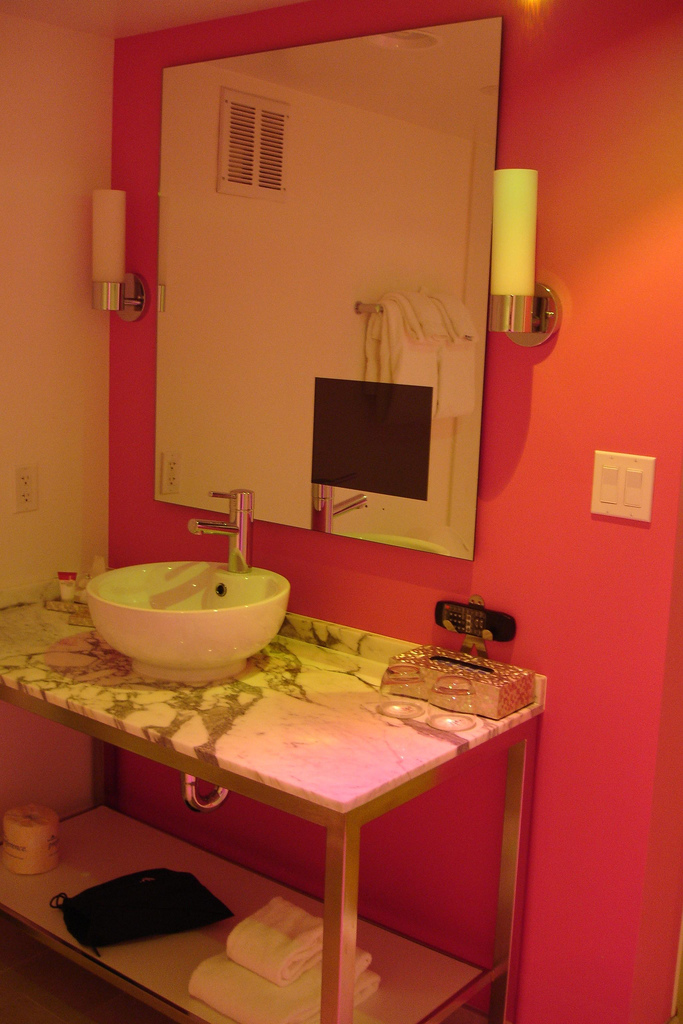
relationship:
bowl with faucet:
[85, 561, 290, 682] [188, 489, 255, 575]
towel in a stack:
[226, 895, 323, 987] [166, 926, 327, 1019]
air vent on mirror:
[207, 79, 291, 198] [153, 15, 501, 563]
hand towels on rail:
[365, 285, 479, 419] [354, 301, 384, 315]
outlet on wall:
[13, 462, 38, 514] [1, 301, 121, 584]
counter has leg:
[4, 599, 554, 821] [305, 808, 373, 1020]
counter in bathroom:
[4, 599, 554, 821] [9, 104, 678, 642]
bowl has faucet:
[85, 561, 290, 682] [181, 473, 261, 569]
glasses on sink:
[365, 647, 484, 733] [84, 553, 293, 684]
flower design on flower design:
[481, 648, 531, 711] [388, 644, 535, 720]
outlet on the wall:
[12, 461, 43, 518] [11, 21, 117, 597]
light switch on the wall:
[586, 442, 658, 527] [96, 32, 661, 1011]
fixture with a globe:
[92, 189, 150, 322] [90, 183, 134, 279]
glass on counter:
[376, 661, 426, 726] [7, 543, 547, 811]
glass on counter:
[422, 671, 479, 731] [4, 599, 554, 821]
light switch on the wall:
[591, 450, 656, 523] [96, 32, 661, 1011]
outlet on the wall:
[13, 462, 38, 514] [8, 47, 109, 892]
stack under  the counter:
[187, 896, 380, 1024] [6, 510, 551, 810]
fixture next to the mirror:
[92, 189, 150, 322] [146, 12, 518, 562]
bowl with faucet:
[85, 561, 290, 682] [183, 486, 258, 569]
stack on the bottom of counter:
[187, 896, 380, 1024] [0, 579, 546, 1024]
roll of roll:
[8, 797, 60, 873] [3, 804, 61, 875]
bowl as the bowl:
[80, 555, 296, 684] [85, 561, 290, 682]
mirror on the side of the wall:
[299, 367, 434, 502] [96, 32, 661, 1011]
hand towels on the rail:
[373, 286, 479, 413] [357, 296, 386, 327]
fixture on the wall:
[86, 183, 143, 334] [96, 32, 661, 1011]